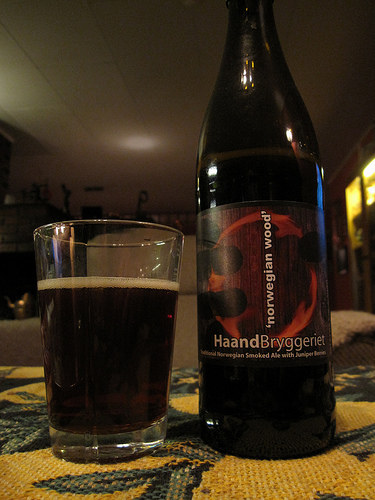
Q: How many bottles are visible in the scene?
A: One.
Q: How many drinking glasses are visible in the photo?
A: One.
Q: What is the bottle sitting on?
A: Tablecloth.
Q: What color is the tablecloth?
A: Yellow and green.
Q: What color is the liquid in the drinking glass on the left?
A: Brown.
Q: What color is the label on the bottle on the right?
A: Maroon, white and black.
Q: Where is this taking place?
A: In a restaurant.